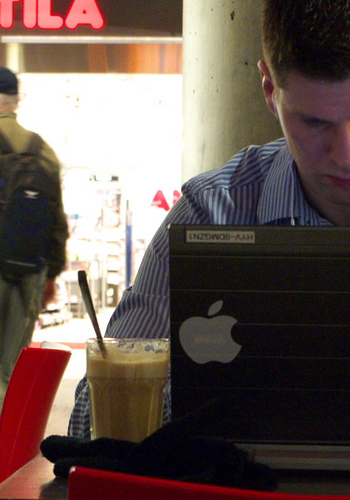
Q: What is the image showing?
A: It is showing a store.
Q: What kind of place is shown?
A: It is a store.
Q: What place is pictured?
A: It is a store.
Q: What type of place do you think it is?
A: It is a store.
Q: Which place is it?
A: It is a store.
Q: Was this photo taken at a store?
A: Yes, it was taken in a store.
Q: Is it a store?
A: Yes, it is a store.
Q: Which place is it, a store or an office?
A: It is a store.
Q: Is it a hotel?
A: No, it is a store.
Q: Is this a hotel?
A: No, it is a store.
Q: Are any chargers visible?
A: No, there are no chargers.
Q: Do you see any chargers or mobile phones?
A: No, there are no chargers or mobile phones.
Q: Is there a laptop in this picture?
A: Yes, there is a laptop.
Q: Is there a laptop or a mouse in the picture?
A: Yes, there is a laptop.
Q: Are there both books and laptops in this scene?
A: No, there is a laptop but no books.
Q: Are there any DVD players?
A: No, there are no DVD players.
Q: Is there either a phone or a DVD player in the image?
A: No, there are no DVD players or phones.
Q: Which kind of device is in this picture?
A: The device is a laptop.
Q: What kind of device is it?
A: The device is a laptop.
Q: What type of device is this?
A: That is a laptop.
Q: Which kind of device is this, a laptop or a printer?
A: That is a laptop.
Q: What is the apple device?
A: The device is a laptop.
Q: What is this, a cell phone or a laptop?
A: This is a laptop.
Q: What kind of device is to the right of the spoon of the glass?
A: The device is a laptop.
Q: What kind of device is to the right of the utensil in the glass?
A: The device is a laptop.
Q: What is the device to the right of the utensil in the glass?
A: The device is a laptop.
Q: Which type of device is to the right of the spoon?
A: The device is a laptop.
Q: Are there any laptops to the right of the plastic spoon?
A: Yes, there is a laptop to the right of the spoon.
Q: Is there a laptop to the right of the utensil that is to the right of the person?
A: Yes, there is a laptop to the right of the spoon.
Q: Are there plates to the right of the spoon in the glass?
A: No, there is a laptop to the right of the spoon.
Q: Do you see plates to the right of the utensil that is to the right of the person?
A: No, there is a laptop to the right of the spoon.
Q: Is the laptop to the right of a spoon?
A: Yes, the laptop is to the right of a spoon.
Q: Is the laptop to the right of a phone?
A: No, the laptop is to the right of a spoon.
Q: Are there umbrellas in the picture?
A: No, there are no umbrellas.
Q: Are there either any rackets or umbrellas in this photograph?
A: No, there are no umbrellas or rackets.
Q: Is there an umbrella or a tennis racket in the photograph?
A: No, there are no umbrellas or rackets.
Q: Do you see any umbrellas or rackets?
A: No, there are no umbrellas or rackets.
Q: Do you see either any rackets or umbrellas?
A: No, there are no umbrellas or rackets.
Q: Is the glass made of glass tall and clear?
A: Yes, the glass is tall and clear.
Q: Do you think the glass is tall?
A: Yes, the glass is tall.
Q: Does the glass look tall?
A: Yes, the glass is tall.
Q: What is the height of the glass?
A: The glass is tall.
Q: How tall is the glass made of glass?
A: The glass is tall.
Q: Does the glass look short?
A: No, the glass is tall.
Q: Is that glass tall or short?
A: The glass is tall.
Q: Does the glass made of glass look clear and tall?
A: Yes, the glass is clear and tall.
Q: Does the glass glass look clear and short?
A: No, the glass is clear but tall.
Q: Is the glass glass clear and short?
A: No, the glass is clear but tall.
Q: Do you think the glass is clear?
A: Yes, the glass is clear.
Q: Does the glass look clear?
A: Yes, the glass is clear.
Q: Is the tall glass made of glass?
A: Yes, the glass is made of glass.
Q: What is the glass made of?
A: The glass is made of glass.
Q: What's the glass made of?
A: The glass is made of glass.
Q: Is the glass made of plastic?
A: No, the glass is made of glass.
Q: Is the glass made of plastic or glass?
A: The glass is made of glass.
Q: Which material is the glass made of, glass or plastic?
A: The glass is made of glass.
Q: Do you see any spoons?
A: Yes, there is a spoon.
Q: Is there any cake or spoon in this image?
A: Yes, there is a spoon.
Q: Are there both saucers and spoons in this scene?
A: No, there is a spoon but no saucers.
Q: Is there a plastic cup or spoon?
A: Yes, there is a plastic spoon.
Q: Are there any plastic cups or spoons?
A: Yes, there is a plastic spoon.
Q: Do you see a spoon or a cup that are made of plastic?
A: Yes, the spoon is made of plastic.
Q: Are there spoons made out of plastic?
A: Yes, there is a spoon that is made of plastic.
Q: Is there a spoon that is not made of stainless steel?
A: Yes, there is a spoon that is made of plastic.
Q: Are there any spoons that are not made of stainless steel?
A: Yes, there is a spoon that is made of plastic.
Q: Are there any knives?
A: No, there are no knives.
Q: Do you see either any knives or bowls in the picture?
A: No, there are no knives or bowls.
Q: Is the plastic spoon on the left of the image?
A: Yes, the spoon is on the left of the image.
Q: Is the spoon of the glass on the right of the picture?
A: No, the spoon is on the left of the image.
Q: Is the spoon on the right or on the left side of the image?
A: The spoon is on the left of the image.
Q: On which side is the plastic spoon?
A: The spoon is on the left of the image.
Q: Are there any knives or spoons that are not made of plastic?
A: No, there is a spoon but it is made of plastic.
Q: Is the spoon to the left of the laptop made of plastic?
A: Yes, the spoon is made of plastic.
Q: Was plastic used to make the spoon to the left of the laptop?
A: Yes, the spoon is made of plastic.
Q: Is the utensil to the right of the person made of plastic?
A: Yes, the spoon is made of plastic.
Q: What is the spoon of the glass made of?
A: The spoon is made of plastic.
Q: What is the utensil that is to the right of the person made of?
A: The spoon is made of plastic.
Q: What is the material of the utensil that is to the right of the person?
A: The spoon is made of plastic.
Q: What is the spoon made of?
A: The spoon is made of plastic.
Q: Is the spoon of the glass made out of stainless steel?
A: No, the spoon is made of plastic.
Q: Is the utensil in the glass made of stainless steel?
A: No, the spoon is made of plastic.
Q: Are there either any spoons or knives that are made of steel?
A: No, there is a spoon but it is made of plastic.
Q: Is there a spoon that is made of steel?
A: No, there is a spoon but it is made of plastic.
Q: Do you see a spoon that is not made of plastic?
A: No, there is a spoon but it is made of plastic.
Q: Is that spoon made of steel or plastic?
A: The spoon is made of plastic.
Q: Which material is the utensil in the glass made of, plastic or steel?
A: The spoon is made of plastic.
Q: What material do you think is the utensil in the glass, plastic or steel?
A: The spoon is made of plastic.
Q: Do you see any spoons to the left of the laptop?
A: Yes, there is a spoon to the left of the laptop.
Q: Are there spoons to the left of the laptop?
A: Yes, there is a spoon to the left of the laptop.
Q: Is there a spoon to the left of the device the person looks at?
A: Yes, there is a spoon to the left of the laptop.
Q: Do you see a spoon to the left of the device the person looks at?
A: Yes, there is a spoon to the left of the laptop.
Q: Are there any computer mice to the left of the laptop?
A: No, there is a spoon to the left of the laptop.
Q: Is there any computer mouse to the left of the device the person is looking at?
A: No, there is a spoon to the left of the laptop.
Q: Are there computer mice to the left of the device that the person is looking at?
A: No, there is a spoon to the left of the laptop.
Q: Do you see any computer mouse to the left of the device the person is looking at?
A: No, there is a spoon to the left of the laptop.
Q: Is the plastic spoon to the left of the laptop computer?
A: Yes, the spoon is to the left of the laptop computer.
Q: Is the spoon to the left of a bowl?
A: No, the spoon is to the left of the laptop computer.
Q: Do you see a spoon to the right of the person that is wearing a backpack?
A: Yes, there is a spoon to the right of the person.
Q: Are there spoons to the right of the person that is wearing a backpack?
A: Yes, there is a spoon to the right of the person.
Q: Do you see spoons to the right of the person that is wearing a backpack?
A: Yes, there is a spoon to the right of the person.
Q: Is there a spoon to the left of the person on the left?
A: No, the spoon is to the right of the person.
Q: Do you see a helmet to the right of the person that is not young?
A: No, there is a spoon to the right of the person.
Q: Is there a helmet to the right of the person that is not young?
A: No, there is a spoon to the right of the person.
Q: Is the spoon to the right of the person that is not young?
A: Yes, the spoon is to the right of the person.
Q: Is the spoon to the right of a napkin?
A: No, the spoon is to the right of the person.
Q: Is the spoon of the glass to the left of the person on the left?
A: No, the spoon is to the right of the person.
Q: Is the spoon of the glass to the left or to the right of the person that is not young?
A: The spoon is to the right of the person.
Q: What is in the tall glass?
A: The spoon is in the glass.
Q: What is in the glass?
A: The spoon is in the glass.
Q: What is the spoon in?
A: The spoon is in the glass.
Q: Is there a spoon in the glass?
A: Yes, there is a spoon in the glass.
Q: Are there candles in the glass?
A: No, there is a spoon in the glass.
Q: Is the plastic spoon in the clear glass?
A: Yes, the spoon is in the glass.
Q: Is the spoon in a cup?
A: No, the spoon is in the glass.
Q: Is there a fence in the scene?
A: No, there are no fences.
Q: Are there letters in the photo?
A: Yes, there are letters.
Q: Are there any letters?
A: Yes, there are letters.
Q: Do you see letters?
A: Yes, there are letters.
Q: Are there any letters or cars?
A: Yes, there are letters.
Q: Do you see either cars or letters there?
A: Yes, there are letters.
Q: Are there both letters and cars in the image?
A: No, there are letters but no cars.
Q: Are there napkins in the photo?
A: No, there are no napkins.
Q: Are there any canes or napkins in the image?
A: No, there are no napkins or canes.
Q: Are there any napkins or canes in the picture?
A: No, there are no napkins or canes.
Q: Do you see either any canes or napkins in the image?
A: No, there are no napkins or canes.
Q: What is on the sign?
A: The letters are on the sign.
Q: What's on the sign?
A: The letters are on the sign.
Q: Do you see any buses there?
A: No, there are no buses.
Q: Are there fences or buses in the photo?
A: No, there are no buses or fences.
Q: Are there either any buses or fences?
A: No, there are no buses or fences.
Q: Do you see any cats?
A: No, there are no cats.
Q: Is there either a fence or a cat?
A: No, there are no cats or fences.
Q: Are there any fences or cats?
A: No, there are no cats or fences.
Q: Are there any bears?
A: No, there are no bears.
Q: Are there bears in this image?
A: No, there are no bears.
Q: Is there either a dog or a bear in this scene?
A: No, there are no bears or dogs.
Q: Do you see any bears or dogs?
A: No, there are no bears or dogs.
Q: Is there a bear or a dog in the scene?
A: No, there are no bears or dogs.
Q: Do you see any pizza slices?
A: No, there are no pizza slices.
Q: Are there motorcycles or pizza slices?
A: No, there are no pizza slices or motorcycles.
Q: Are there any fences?
A: No, there are no fences.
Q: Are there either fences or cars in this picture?
A: No, there are no fences or cars.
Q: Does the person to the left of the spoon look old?
A: Yes, the person is old.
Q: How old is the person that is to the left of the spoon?
A: The person is old.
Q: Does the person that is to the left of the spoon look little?
A: No, the person is old.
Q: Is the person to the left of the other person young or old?
A: The person is old.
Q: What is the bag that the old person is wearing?
A: The bag is a backpack.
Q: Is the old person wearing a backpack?
A: Yes, the person is wearing a backpack.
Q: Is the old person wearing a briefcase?
A: No, the person is wearing a backpack.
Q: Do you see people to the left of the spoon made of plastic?
A: Yes, there is a person to the left of the spoon.